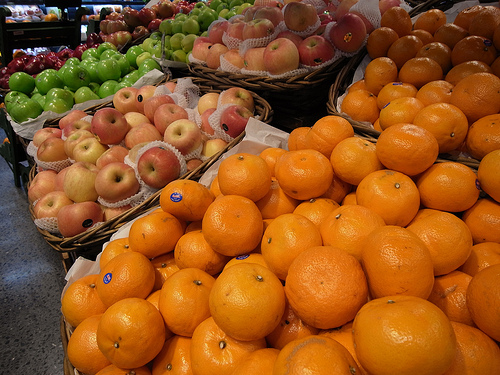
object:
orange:
[261, 210, 323, 280]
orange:
[160, 265, 216, 337]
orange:
[374, 123, 441, 176]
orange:
[209, 260, 288, 341]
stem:
[253, 272, 264, 282]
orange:
[217, 151, 271, 202]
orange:
[97, 296, 167, 369]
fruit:
[281, 245, 370, 330]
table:
[1, 20, 82, 65]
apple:
[152, 102, 189, 137]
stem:
[113, 171, 120, 181]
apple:
[10, 98, 41, 120]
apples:
[264, 38, 300, 74]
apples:
[331, 14, 367, 56]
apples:
[216, 105, 254, 135]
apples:
[93, 105, 127, 142]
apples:
[204, 42, 229, 68]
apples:
[299, 33, 335, 65]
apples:
[243, 17, 277, 47]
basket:
[186, 59, 342, 94]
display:
[0, 0, 500, 374]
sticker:
[103, 268, 113, 287]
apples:
[217, 151, 272, 203]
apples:
[93, 162, 139, 204]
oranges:
[157, 178, 215, 220]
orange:
[351, 294, 463, 374]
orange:
[276, 150, 337, 203]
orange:
[200, 193, 265, 258]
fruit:
[354, 167, 422, 227]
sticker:
[80, 216, 97, 230]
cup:
[97, 192, 153, 209]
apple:
[7, 70, 35, 93]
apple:
[56, 200, 102, 236]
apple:
[94, 160, 143, 201]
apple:
[135, 144, 183, 189]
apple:
[71, 137, 105, 165]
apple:
[163, 118, 202, 155]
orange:
[90, 252, 154, 308]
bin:
[0, 56, 175, 132]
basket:
[26, 75, 274, 271]